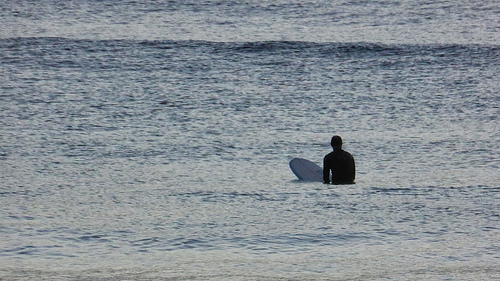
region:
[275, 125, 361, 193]
person sitting on a surfboard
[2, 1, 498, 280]
large body of water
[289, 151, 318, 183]
surfboard sticking out of the water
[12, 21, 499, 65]
small wave on the water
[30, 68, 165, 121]
small ripples on the water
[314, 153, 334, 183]
arm is down by side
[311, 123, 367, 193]
silhouette of a person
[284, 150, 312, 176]
tip of the surfboard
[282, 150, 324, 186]
white surfboard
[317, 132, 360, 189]
torso sticking out of the water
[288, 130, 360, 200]
a man in the water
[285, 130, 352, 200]
a man in the water on a board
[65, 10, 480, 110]
A smal ocean wave forming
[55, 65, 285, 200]
Ripples aross the water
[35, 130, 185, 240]
the water is deep blue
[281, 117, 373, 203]
a man waiting on a wave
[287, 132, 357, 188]
a man waiting on a white surf board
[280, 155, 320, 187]
A white surf board in the water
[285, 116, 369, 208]
A man waiting on a wave near dusk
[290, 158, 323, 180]
A symbol on surf board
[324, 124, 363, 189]
man in the ocean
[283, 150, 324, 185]
top of surfboard in the ocean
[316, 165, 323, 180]
logo on the surfboard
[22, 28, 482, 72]
ocean wave coming in to shore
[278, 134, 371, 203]
man sitting on surfboard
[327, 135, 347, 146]
head on the man's shoulder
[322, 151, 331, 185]
left arm on the man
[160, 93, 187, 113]
dark wave in the water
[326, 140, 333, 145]
left ear of the surfer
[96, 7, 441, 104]
ocean water in the distance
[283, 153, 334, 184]
tip of surfboard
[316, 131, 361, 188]
Surfer observing incoming waves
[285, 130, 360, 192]
Surfer sitting on surfboard in ocean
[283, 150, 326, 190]
Surfboard sticking out of the water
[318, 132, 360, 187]
Surfer wearing a wetsuit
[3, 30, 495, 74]
Wave on the ocean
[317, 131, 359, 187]
Back view of a surfer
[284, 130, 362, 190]
Man straddling a surfboard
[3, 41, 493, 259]
Lone surfer in ocean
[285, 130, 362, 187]
Surfer waiting for a wave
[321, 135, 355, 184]
Man in the ocean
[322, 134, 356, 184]
Man sitting on surf board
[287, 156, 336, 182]
White colored surf board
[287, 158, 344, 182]
Surf board beneath man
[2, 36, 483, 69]
Wave forming in ocean towards man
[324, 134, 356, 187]
Man looking out into the ocean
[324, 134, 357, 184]
Man waiting for the next wave to come in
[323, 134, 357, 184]
Man alone in the ocean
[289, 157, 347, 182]
White surf board in the ocean holding a surfer